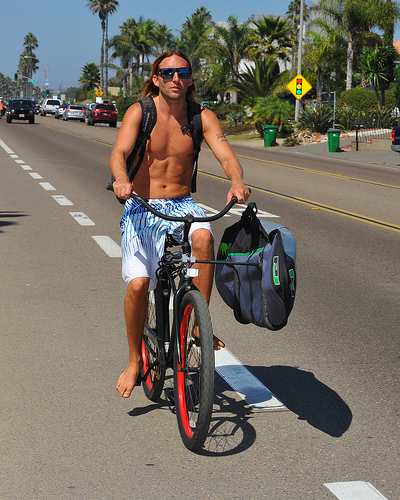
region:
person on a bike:
[86, 48, 302, 416]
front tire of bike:
[172, 289, 245, 458]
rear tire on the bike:
[127, 296, 163, 403]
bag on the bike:
[213, 205, 303, 332]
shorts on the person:
[115, 196, 220, 272]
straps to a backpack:
[105, 95, 210, 187]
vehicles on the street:
[2, 82, 117, 140]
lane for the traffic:
[44, 133, 74, 175]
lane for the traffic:
[341, 180, 370, 212]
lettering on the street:
[165, 194, 275, 226]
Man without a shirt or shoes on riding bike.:
[107, 49, 296, 452]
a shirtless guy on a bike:
[110, 40, 273, 444]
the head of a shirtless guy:
[139, 52, 205, 114]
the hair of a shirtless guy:
[139, 65, 160, 92]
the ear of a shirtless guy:
[148, 67, 162, 93]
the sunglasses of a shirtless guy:
[156, 67, 190, 80]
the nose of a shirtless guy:
[165, 65, 181, 82]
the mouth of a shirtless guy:
[164, 80, 184, 91]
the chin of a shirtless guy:
[168, 86, 192, 102]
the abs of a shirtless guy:
[145, 108, 191, 197]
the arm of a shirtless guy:
[198, 108, 264, 189]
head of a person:
[148, 41, 206, 108]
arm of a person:
[92, 118, 148, 202]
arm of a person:
[220, 129, 254, 186]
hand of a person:
[105, 171, 154, 207]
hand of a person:
[218, 182, 258, 217]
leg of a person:
[101, 284, 157, 378]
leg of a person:
[175, 249, 221, 319]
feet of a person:
[106, 357, 141, 394]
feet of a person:
[184, 319, 240, 356]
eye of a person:
[156, 63, 190, 81]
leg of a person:
[184, 245, 241, 304]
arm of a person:
[189, 125, 266, 189]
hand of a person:
[95, 181, 159, 202]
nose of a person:
[166, 76, 188, 85]